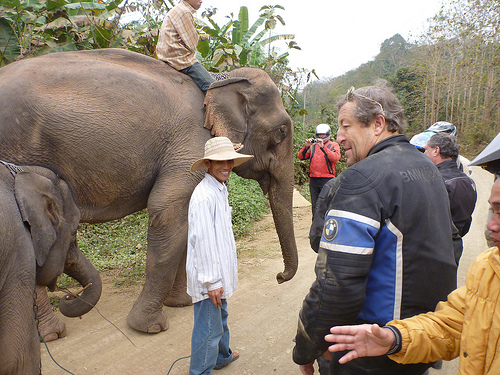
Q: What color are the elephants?
A: Brown.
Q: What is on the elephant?
A: A man.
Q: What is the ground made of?
A: Dirt.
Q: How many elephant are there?
A: Two.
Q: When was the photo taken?
A: Day time.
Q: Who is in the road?
A: The pedestrians.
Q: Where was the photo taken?
A: On sightseeing tour.